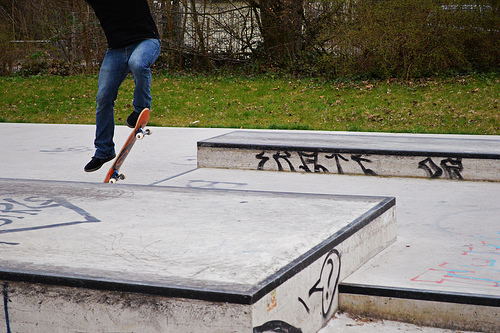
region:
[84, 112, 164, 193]
skatting machine by men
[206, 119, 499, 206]
a large bench for skating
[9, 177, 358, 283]
vast space of the bench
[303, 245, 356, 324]
beautiful design draw on the bench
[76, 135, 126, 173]
leg of the men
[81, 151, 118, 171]
shoe of the men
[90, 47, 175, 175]
jeans pant of the men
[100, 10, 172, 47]
black shirt of the men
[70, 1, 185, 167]
a man skating in air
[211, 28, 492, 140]
green grass on the field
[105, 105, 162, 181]
this is a skateboard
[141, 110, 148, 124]
the skateboard is orange in color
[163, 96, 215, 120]
this is the grass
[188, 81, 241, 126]
the grass is green in color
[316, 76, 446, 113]
these are some leaves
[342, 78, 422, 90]
the leaves are dry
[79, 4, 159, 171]
this is a man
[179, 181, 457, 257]
this is a skating zone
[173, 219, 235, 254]
the ground is grey in color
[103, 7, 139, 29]
the t-shirt is black in color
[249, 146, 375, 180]
graffiti on a cement block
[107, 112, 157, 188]
a skateboard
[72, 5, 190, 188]
Young man riding a skateboard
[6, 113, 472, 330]
a skateboard use area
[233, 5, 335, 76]
a tree in a grassy area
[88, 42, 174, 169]
blue jean pants on a young man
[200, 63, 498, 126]
grass next to a skateboard area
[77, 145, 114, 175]
a shoe worn by a skateboarder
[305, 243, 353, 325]
graffiti in a skateboard area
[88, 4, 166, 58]
a black short worn by a young skateboarder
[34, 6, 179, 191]
person wearing black t-shirt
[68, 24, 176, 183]
person wearing blue jeans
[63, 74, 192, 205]
person doing a skateboarding trick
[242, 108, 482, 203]
black paint grafitti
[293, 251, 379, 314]
question mark sprayed on cement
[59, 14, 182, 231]
person wearing back shoes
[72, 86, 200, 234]
skateboard with white wheels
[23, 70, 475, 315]
cement skateboarding park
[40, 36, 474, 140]
grass with dead leaves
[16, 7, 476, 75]
tree branches with no leaves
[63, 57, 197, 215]
both feet off the board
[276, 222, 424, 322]
a question mark graffiti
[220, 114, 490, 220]
black graffiti on cement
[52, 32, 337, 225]
the jeans are blue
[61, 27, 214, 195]
the board is mid air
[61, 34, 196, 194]
performing a skateboarding trick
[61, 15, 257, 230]
the art of skating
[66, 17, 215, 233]
the shirt is black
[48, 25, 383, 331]
skating off a metal rim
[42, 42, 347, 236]
the steps are concrete